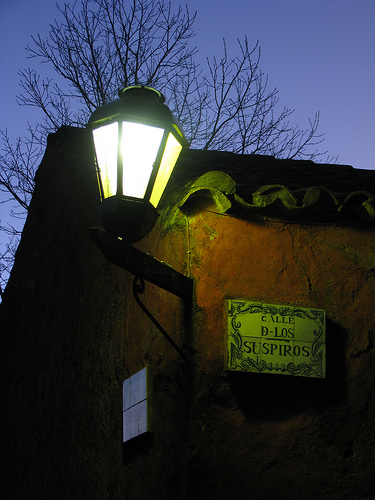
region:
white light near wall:
[83, 118, 174, 229]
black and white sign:
[231, 279, 319, 393]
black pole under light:
[97, 238, 199, 386]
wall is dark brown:
[187, 205, 306, 291]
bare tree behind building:
[33, 7, 351, 167]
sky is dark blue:
[302, 6, 356, 131]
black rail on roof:
[192, 171, 372, 216]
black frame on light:
[95, 93, 173, 217]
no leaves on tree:
[57, 18, 259, 124]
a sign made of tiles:
[219, 285, 347, 402]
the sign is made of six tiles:
[218, 287, 341, 386]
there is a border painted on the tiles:
[226, 291, 333, 381]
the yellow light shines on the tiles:
[214, 284, 343, 389]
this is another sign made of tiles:
[106, 361, 167, 453]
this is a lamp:
[79, 49, 202, 263]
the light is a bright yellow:
[66, 62, 212, 272]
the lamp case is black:
[71, 52, 189, 241]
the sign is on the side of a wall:
[208, 277, 354, 387]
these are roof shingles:
[191, 131, 373, 214]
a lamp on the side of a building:
[53, 82, 199, 311]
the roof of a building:
[189, 146, 369, 233]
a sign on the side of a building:
[219, 290, 333, 387]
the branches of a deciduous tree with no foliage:
[14, 3, 359, 161]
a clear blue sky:
[279, 0, 372, 95]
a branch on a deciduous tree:
[200, 36, 264, 149]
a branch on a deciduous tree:
[0, 158, 28, 209]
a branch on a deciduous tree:
[13, 63, 59, 135]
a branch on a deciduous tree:
[149, 14, 192, 86]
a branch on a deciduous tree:
[64, 6, 110, 104]